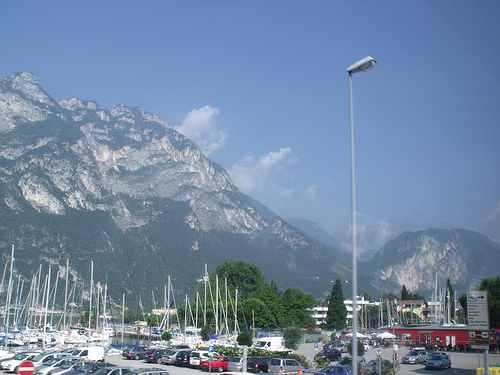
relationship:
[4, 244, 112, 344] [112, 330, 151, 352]
boats in water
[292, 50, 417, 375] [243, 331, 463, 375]
light hanging over street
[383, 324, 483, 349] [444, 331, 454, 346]
building with doors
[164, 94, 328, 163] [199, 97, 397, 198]
clouds in sky